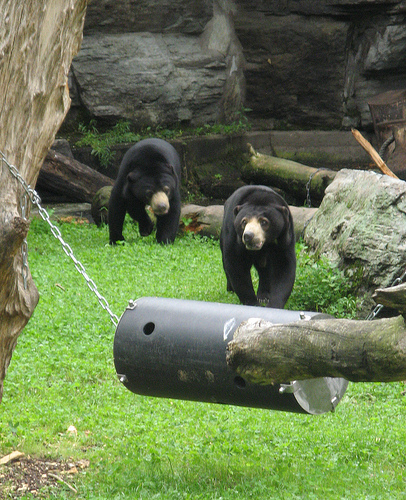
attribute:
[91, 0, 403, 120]
wall — smooth, tall, brick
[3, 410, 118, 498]
dirt — brown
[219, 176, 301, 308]
bear — brown, black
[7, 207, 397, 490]
grass — green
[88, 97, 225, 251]
bear — black 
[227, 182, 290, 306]
bear — black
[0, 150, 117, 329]
metal chain — long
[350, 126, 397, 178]
branch — brown, long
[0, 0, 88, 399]
tree — tall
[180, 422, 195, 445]
ground — grassy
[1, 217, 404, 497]
ground — grassy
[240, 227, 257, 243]
nose — Black 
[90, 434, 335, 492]
ground — grassy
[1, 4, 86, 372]
tree trunk — large 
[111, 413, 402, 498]
ground — grassy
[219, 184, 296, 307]
bear — black, circular, Long 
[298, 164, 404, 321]
rock — big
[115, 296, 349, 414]
can — big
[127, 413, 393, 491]
grass — green